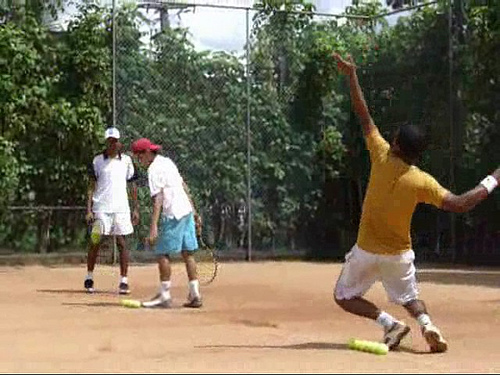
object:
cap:
[131, 138, 162, 152]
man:
[328, 48, 499, 353]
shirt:
[355, 127, 448, 256]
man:
[132, 136, 206, 310]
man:
[82, 126, 141, 296]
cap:
[103, 127, 121, 139]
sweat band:
[481, 173, 498, 192]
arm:
[421, 165, 499, 215]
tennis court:
[2, 259, 499, 374]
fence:
[109, 1, 499, 260]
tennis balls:
[346, 335, 390, 357]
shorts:
[155, 212, 200, 257]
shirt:
[83, 150, 139, 215]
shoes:
[419, 321, 448, 353]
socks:
[414, 313, 432, 326]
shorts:
[334, 243, 420, 305]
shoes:
[117, 279, 133, 294]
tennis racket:
[196, 222, 219, 287]